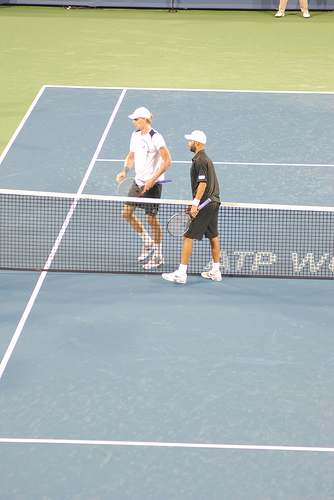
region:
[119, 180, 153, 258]
the leg of the tennis player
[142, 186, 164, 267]
the leg of the tennis player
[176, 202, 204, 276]
the leg of the tennis player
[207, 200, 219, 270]
the leg of the tennis player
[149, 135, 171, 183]
the arm of the tennis player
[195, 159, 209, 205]
the arm of the tennis player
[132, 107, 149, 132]
the head of the tennis player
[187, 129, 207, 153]
the head of the tennis player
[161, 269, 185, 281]
the white tennis shoe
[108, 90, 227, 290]
players with tennis racket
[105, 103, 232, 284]
players with tennis racket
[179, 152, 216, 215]
the shirt is black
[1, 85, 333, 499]
blue and white tennis court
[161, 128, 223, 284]
male tennis player dressed in all black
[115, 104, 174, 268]
male tennis player with blonde hair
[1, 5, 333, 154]
green out of bounds area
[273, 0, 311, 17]
legs and feet of an onlooker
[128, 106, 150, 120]
white baseball cap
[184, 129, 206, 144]
white baseball cap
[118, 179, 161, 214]
men's black tennis shorts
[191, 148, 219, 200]
man's black tennis shirt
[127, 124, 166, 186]
man's white and purple tennis shirt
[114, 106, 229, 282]
two men playing tennis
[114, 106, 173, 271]
a man wearing a white shirt and black shorts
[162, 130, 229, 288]
a man wearing a black shirt and shorts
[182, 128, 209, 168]
a man with a beard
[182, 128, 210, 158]
a man wearing a white ball cap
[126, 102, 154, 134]
a man wearing a white ball cap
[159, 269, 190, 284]
a white tennis shoe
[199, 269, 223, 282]
a white tennis shoe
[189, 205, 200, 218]
a hand of a man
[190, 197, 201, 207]
a white wrist band on a wrist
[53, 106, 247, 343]
the court is blue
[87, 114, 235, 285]
they are playing tennis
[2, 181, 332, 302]
the net is black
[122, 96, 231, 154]
both hats are white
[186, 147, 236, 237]
his outfit is black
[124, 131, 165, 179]
his shirt is white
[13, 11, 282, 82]
out of bounds is green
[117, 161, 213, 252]
Both holding tennis rackets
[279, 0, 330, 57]
Another set of legs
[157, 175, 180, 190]
racket handle is blue